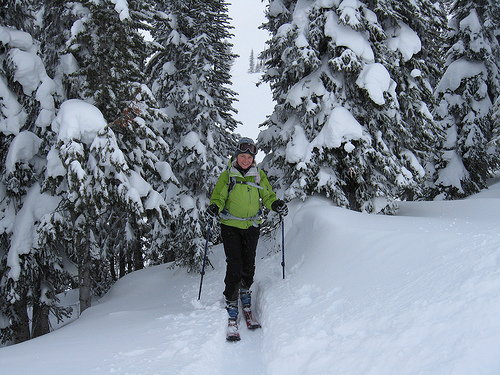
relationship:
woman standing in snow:
[207, 138, 289, 312] [334, 264, 445, 364]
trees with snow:
[0, 0, 498, 344] [0, 2, 497, 373]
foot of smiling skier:
[240, 300, 261, 318] [191, 136, 293, 321]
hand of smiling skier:
[203, 205, 218, 222] [204, 138, 288, 345]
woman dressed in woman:
[207, 138, 289, 312] [207, 138, 289, 312]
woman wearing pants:
[207, 138, 289, 312] [218, 222, 263, 301]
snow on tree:
[261, 11, 500, 209] [21, 25, 160, 279]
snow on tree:
[13, 47, 35, 76] [21, 25, 160, 279]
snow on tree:
[7, 211, 34, 238] [280, 4, 497, 204]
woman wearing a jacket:
[207, 138, 289, 312] [206, 169, 273, 231]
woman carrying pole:
[206, 136, 288, 344] [191, 205, 218, 307]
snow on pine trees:
[318, 31, 402, 128] [8, 12, 463, 152]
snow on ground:
[316, 285, 433, 358] [326, 235, 428, 315]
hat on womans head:
[230, 138, 257, 155] [235, 150, 252, 169]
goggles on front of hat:
[237, 143, 260, 153] [233, 136, 257, 156]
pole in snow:
[280, 217, 287, 277] [285, 220, 495, 373]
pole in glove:
[198, 219, 212, 300] [202, 201, 219, 219]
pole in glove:
[279, 215, 287, 279] [274, 200, 292, 222]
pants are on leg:
[222, 221, 259, 303] [223, 230, 245, 307]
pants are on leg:
[222, 221, 259, 303] [239, 229, 260, 291]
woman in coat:
[207, 138, 289, 312] [214, 164, 279, 228]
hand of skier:
[270, 198, 290, 215] [166, 116, 318, 329]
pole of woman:
[198, 219, 212, 300] [207, 138, 289, 312]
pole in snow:
[176, 219, 241, 298] [24, 196, 483, 359]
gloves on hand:
[263, 197, 290, 222] [272, 200, 287, 211]